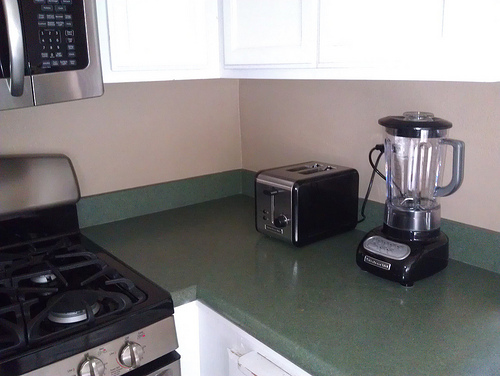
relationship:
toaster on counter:
[220, 99, 383, 251] [99, 209, 497, 367]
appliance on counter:
[354, 110, 464, 286] [99, 209, 497, 367]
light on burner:
[137, 332, 147, 341] [7, 237, 86, 339]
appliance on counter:
[252, 159, 359, 247] [154, 186, 489, 374]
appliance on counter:
[253, 143, 365, 248] [154, 186, 489, 374]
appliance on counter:
[368, 101, 467, 288] [154, 186, 489, 374]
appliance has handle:
[354, 110, 464, 286] [440, 131, 462, 196]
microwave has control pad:
[0, 2, 107, 109] [25, 2, 82, 70]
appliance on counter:
[252, 159, 359, 247] [335, 312, 437, 365]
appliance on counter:
[354, 110, 464, 286] [76, 167, 498, 374]